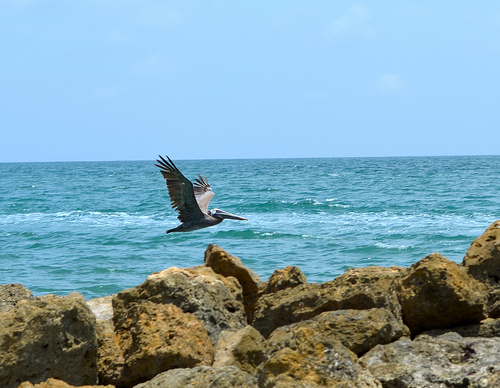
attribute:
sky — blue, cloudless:
[263, 70, 421, 136]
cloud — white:
[327, 8, 370, 40]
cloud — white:
[361, 68, 408, 101]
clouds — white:
[323, 5, 408, 96]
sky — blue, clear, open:
[2, 0, 496, 161]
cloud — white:
[323, 4, 380, 45]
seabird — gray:
[147, 149, 253, 244]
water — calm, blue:
[1, 151, 498, 304]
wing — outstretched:
[153, 153, 204, 221]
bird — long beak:
[132, 148, 257, 240]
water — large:
[6, 164, 496, 256]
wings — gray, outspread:
[152, 150, 240, 237]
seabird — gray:
[156, 153, 248, 233]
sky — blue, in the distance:
[75, 26, 460, 124]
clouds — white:
[327, 4, 425, 114]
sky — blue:
[29, 44, 311, 139]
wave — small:
[255, 180, 338, 239]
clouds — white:
[7, 58, 130, 140]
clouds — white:
[304, 6, 472, 142]